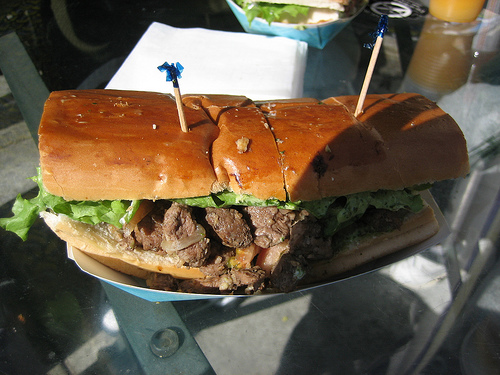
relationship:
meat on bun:
[123, 218, 166, 256] [27, 60, 497, 193]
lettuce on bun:
[1, 183, 435, 247] [37, 86, 471, 197]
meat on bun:
[123, 218, 333, 277] [46, 75, 463, 190]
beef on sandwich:
[189, 204, 268, 231] [113, 191, 423, 297]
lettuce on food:
[3, 165, 435, 237] [36, 86, 470, 295]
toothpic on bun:
[350, 10, 383, 117] [37, 86, 471, 197]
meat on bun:
[160, 201, 210, 267] [37, 86, 471, 197]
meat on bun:
[207, 205, 254, 247] [37, 86, 471, 197]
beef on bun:
[249, 208, 285, 245] [37, 86, 471, 197]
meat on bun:
[294, 214, 342, 249] [341, 240, 401, 274]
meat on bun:
[176, 212, 361, 249] [27, 77, 466, 206]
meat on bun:
[176, 212, 361, 249] [51, 205, 445, 288]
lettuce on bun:
[0, 166, 420, 241] [37, 86, 471, 197]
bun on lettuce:
[34, 201, 438, 287] [0, 166, 420, 241]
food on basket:
[37, 29, 484, 315] [53, 187, 449, 311]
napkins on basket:
[223, 37, 285, 64] [53, 187, 449, 311]